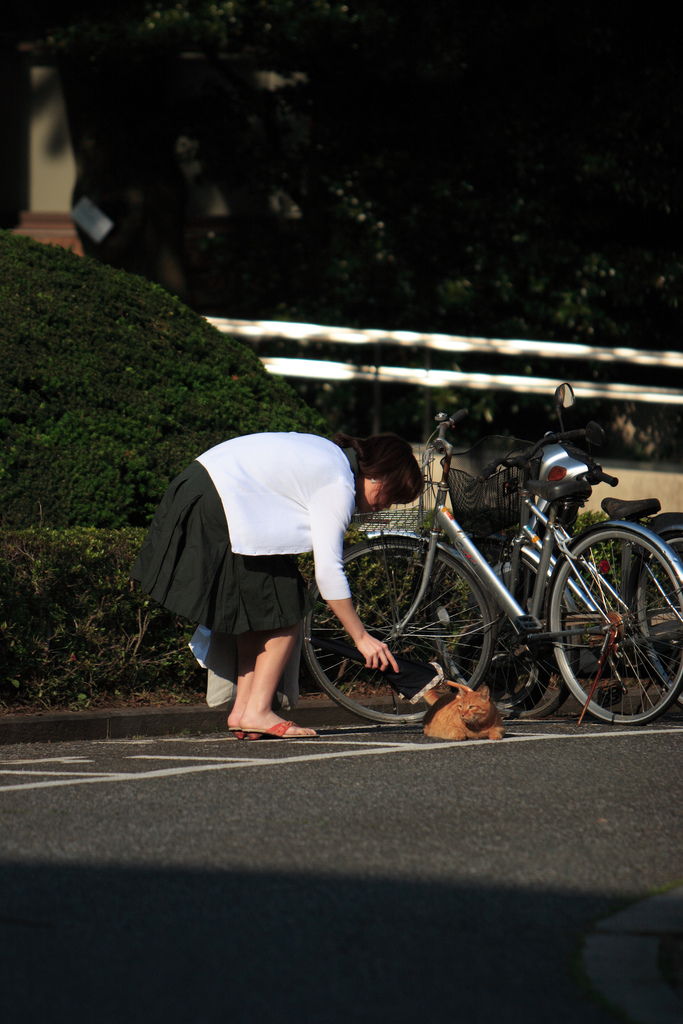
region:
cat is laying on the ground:
[415, 677, 505, 741]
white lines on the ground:
[4, 701, 682, 801]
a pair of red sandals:
[227, 704, 321, 740]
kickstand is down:
[570, 614, 610, 733]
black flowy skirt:
[127, 449, 323, 647]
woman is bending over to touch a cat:
[133, 395, 531, 748]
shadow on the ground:
[1, 848, 638, 1022]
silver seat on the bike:
[541, 444, 596, 502]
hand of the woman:
[334, 626, 408, 672]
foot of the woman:
[234, 712, 301, 745]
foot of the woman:
[214, 708, 243, 738]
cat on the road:
[412, 688, 501, 728]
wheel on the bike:
[568, 683, 648, 719]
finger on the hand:
[389, 651, 405, 674]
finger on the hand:
[357, 656, 376, 666]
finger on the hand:
[364, 644, 379, 663]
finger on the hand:
[367, 646, 389, 668]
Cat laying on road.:
[407, 666, 527, 761]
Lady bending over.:
[94, 407, 432, 760]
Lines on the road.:
[15, 729, 226, 840]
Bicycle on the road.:
[301, 381, 679, 740]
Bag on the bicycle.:
[429, 435, 547, 564]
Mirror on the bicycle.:
[533, 363, 606, 471]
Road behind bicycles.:
[423, 314, 677, 735]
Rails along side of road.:
[289, 296, 681, 508]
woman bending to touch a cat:
[126, 433, 503, 745]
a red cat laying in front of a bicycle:
[302, 383, 681, 740]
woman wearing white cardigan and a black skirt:
[127, 429, 426, 744]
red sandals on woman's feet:
[226, 708, 316, 744]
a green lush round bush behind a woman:
[0, 228, 425, 743]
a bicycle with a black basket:
[442, 380, 679, 718]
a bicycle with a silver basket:
[304, 405, 679, 726]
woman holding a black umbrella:
[129, 431, 476, 738]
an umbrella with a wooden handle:
[302, 634, 471, 699]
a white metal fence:
[203, 313, 680, 513]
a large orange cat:
[419, 681, 506, 744]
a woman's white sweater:
[190, 426, 358, 610]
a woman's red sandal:
[244, 714, 320, 741]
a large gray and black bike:
[295, 413, 681, 728]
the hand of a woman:
[356, 632, 405, 673]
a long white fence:
[184, 301, 681, 402]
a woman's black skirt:
[129, 458, 315, 637]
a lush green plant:
[11, 238, 72, 306]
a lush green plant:
[0, 321, 65, 420]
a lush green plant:
[217, 349, 289, 431]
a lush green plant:
[75, 407, 157, 511]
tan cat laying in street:
[416, 671, 509, 751]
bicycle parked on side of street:
[290, 394, 680, 733]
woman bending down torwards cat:
[120, 426, 512, 760]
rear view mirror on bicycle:
[547, 380, 583, 427]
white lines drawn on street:
[0, 725, 681, 801]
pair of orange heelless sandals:
[221, 711, 324, 748]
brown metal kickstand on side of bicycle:
[569, 604, 622, 728]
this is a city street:
[52, 131, 602, 855]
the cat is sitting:
[400, 661, 550, 770]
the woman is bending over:
[179, 394, 420, 692]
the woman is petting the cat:
[141, 404, 507, 751]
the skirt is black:
[118, 470, 305, 623]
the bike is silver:
[388, 489, 649, 643]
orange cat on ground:
[422, 675, 505, 737]